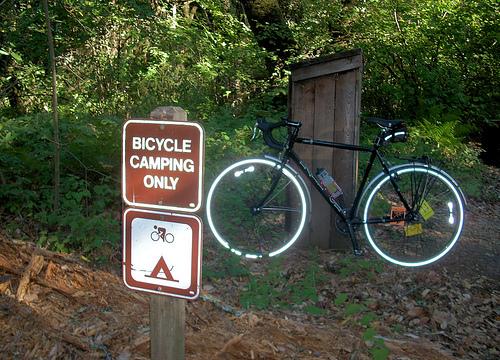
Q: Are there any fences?
A: No, there are no fences.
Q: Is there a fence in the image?
A: No, there are no fences.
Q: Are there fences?
A: No, there are no fences.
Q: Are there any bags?
A: No, there are no bags.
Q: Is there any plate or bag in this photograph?
A: No, there are no bags or plates.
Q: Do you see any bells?
A: No, there are no bells.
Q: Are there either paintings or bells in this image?
A: No, there are no bells or paintings.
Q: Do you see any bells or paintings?
A: No, there are no bells or paintings.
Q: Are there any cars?
A: No, there are no cars.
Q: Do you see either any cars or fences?
A: No, there are no cars or fences.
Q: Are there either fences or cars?
A: No, there are no cars or fences.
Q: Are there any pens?
A: No, there are no pens.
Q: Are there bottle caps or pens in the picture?
A: No, there are no pens or bottle caps.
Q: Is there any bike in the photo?
A: Yes, there is a bike.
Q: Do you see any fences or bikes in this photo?
A: Yes, there is a bike.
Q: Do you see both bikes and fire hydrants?
A: No, there is a bike but no fire hydrants.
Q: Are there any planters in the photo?
A: No, there are no planters.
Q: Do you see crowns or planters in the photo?
A: No, there are no planters or crowns.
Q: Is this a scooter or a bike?
A: This is a bike.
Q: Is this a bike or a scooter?
A: This is a bike.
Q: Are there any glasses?
A: No, there are no glasses.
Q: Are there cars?
A: No, there are no cars.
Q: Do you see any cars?
A: No, there are no cars.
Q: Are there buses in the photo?
A: No, there are no buses.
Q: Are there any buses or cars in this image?
A: No, there are no buses or cars.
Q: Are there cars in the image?
A: No, there are no cars.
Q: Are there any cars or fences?
A: No, there are no cars or fences.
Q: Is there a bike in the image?
A: Yes, there is a bike.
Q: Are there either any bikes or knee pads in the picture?
A: Yes, there is a bike.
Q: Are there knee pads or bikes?
A: Yes, there is a bike.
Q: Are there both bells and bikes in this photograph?
A: No, there is a bike but no bells.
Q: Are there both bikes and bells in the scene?
A: No, there is a bike but no bells.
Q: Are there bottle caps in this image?
A: No, there are no bottle caps.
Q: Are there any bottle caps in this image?
A: No, there are no bottle caps.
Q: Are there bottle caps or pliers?
A: No, there are no bottle caps or pliers.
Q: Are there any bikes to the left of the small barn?
A: Yes, there is a bike to the left of the barn.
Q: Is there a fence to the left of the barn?
A: No, there is a bike to the left of the barn.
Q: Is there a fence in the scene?
A: No, there are no fences.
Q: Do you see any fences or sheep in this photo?
A: No, there are no fences or sheep.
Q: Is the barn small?
A: Yes, the barn is small.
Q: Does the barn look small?
A: Yes, the barn is small.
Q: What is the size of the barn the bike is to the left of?
A: The barn is small.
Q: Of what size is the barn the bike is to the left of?
A: The barn is small.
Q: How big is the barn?
A: The barn is small.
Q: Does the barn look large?
A: No, the barn is small.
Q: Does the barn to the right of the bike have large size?
A: No, the barn is small.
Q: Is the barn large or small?
A: The barn is small.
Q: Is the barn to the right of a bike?
A: Yes, the barn is to the right of a bike.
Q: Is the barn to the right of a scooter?
A: No, the barn is to the right of a bike.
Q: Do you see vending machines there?
A: No, there are no vending machines.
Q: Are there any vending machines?
A: No, there are no vending machines.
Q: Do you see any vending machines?
A: No, there are no vending machines.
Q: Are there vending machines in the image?
A: No, there are no vending machines.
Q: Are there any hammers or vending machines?
A: No, there are no vending machines or hammers.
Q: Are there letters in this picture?
A: Yes, there are letters.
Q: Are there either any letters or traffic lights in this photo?
A: Yes, there are letters.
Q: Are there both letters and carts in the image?
A: No, there are letters but no carts.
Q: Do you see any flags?
A: No, there are no flags.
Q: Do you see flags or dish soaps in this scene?
A: No, there are no flags or dish soaps.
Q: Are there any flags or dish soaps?
A: No, there are no flags or dish soaps.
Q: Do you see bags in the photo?
A: No, there are no bags.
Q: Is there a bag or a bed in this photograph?
A: No, there are no bags or beds.